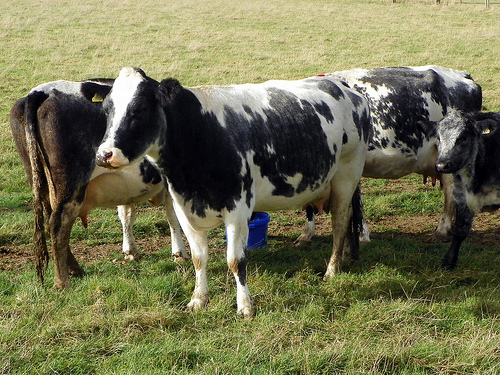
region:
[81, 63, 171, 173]
A cows front face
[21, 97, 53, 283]
A cows long tail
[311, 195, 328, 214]
A cows pink utter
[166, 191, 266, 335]
A cows front legs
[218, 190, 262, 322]
Cow front left leg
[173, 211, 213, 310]
Cow front right leg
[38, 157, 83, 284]
Cow back right leg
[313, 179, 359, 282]
Cow back left leg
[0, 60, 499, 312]
A group of cows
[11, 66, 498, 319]
A group of cows in a field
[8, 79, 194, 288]
cow is next to cow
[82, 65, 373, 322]
cow is next to cow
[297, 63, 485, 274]
cow is next to cow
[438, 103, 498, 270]
cow is next to cow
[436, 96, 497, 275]
cow is standing on grass field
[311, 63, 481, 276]
cow is standing on grass field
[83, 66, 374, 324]
cow is standing on grass field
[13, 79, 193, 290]
cow is standing on grass field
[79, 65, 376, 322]
cow is in front of cow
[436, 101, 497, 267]
cow is in front of cow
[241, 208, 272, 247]
Blue pail under the cows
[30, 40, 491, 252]
cows in the field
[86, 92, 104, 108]
cow with a yellow tag in its ear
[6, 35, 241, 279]
cows in the field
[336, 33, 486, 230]
cows in the field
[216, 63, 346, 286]
cows in the field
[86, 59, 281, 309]
cows in the field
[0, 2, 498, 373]
green field underneath cow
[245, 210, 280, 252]
blue bucket under cow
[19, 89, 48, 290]
black tail on cow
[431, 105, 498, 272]
small cow next to cow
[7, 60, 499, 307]
Several cows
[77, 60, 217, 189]
This cow is facing the camera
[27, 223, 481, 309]
The cows are standing in grass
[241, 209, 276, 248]
A blue bucket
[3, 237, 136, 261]
A patch of dirt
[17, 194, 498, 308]
All of the cows are standing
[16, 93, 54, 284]
The cow's tail goes to the ground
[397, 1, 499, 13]
Bottom of a fence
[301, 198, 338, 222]
The cow's nipples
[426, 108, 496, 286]
A small calf